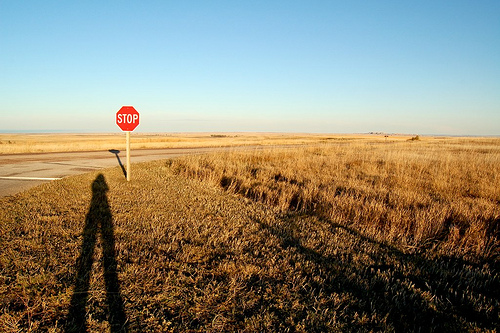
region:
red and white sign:
[94, 93, 154, 171]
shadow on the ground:
[46, 139, 143, 253]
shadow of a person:
[52, 138, 137, 264]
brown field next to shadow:
[320, 156, 426, 236]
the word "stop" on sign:
[109, 101, 147, 131]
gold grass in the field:
[284, 151, 374, 217]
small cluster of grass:
[226, 176, 238, 194]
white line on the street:
[25, 169, 70, 189]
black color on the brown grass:
[147, 247, 189, 282]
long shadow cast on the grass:
[81, 162, 128, 327]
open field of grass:
[163, 124, 238, 142]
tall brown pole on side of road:
[122, 130, 139, 185]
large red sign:
[106, 103, 148, 140]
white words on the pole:
[114, 108, 145, 125]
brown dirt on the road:
[21, 152, 91, 169]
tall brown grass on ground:
[177, 155, 195, 173]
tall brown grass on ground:
[231, 163, 236, 168]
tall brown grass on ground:
[290, 173, 292, 177]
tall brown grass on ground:
[317, 191, 334, 201]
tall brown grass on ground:
[365, 216, 369, 220]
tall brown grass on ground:
[427, 176, 451, 193]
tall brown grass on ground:
[392, 162, 403, 170]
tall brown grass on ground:
[490, 145, 498, 206]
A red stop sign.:
[106, 95, 163, 150]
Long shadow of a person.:
[59, 166, 149, 331]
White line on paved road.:
[1, 170, 63, 185]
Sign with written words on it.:
[106, 95, 154, 185]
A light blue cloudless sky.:
[1, 55, 496, 105]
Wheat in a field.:
[304, 146, 489, 188]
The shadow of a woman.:
[43, 170, 130, 330]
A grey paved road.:
[1, 154, 119, 174]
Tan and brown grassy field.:
[178, 269, 469, 329]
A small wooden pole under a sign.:
[123, 129, 136, 186]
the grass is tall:
[141, 209, 203, 254]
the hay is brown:
[338, 170, 427, 227]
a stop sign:
[110, 103, 143, 130]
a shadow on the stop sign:
[105, 141, 125, 174]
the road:
[29, 158, 64, 178]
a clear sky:
[151, 26, 218, 78]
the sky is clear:
[199, 42, 276, 99]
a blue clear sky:
[301, 37, 368, 80]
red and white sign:
[109, 105, 145, 135]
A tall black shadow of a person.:
[70, 174, 130, 331]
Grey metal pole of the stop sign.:
[125, 129, 130, 180]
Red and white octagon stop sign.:
[113, 105, 138, 132]